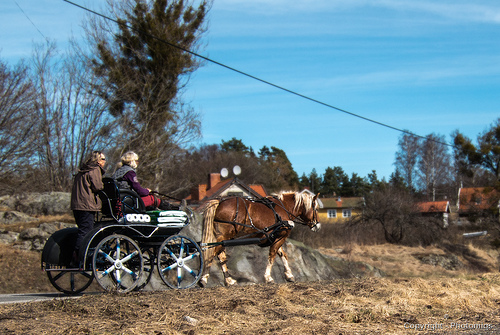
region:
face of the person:
[66, 140, 160, 176]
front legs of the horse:
[245, 225, 324, 303]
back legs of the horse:
[200, 244, 247, 291]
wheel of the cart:
[87, 221, 148, 298]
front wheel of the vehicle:
[146, 211, 213, 315]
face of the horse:
[295, 175, 337, 270]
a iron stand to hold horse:
[201, 223, 280, 253]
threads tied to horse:
[230, 180, 317, 225]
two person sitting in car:
[65, 148, 164, 237]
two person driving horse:
[61, 119, 194, 248]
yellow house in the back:
[317, 192, 365, 221]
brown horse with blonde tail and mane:
[202, 187, 322, 281]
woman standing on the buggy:
[69, 150, 104, 265]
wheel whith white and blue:
[93, 233, 143, 291]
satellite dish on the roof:
[220, 166, 230, 178]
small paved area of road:
[3, 291, 84, 305]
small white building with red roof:
[410, 200, 451, 230]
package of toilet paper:
[121, 213, 151, 220]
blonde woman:
[113, 146, 189, 208]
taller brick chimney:
[208, 169, 219, 186]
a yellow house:
[320, 193, 367, 220]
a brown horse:
[200, 186, 325, 279]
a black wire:
[81, 5, 495, 180]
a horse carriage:
[64, 145, 315, 292]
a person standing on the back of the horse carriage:
[73, 145, 111, 256]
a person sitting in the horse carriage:
[112, 145, 175, 209]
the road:
[2, 288, 83, 305]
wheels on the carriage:
[100, 235, 199, 287]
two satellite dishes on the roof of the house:
[217, 160, 245, 171]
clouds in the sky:
[285, 10, 442, 65]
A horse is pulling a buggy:
[15, 130, 355, 325]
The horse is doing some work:
[15, 127, 355, 322]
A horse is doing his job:
[31, 112, 357, 322]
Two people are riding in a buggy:
[28, 112, 368, 313]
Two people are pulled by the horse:
[15, 135, 398, 318]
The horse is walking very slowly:
[31, 128, 356, 309]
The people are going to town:
[26, 117, 379, 328]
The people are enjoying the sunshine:
[16, 95, 401, 320]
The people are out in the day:
[25, 112, 440, 314]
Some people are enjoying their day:
[29, 106, 432, 324]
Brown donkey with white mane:
[186, 186, 326, 288]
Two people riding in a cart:
[64, 148, 179, 228]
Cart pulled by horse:
[36, 213, 266, 295]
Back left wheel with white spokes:
[90, 231, 148, 293]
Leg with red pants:
[136, 190, 173, 209]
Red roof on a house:
[453, 188, 498, 210]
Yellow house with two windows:
[309, 193, 365, 222]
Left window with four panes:
[329, 208, 336, 218]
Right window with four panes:
[341, 207, 352, 218]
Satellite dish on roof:
[232, 165, 243, 176]